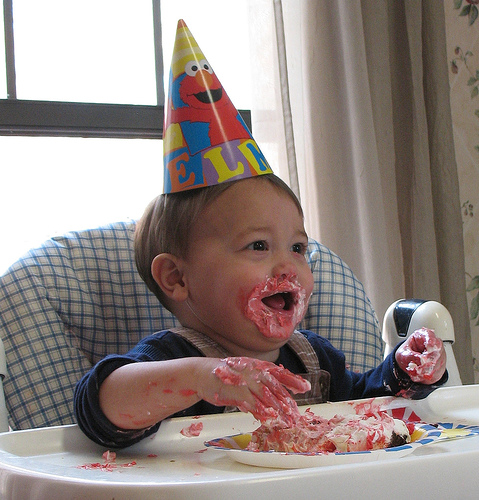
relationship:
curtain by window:
[305, 4, 479, 387] [1, 2, 321, 267]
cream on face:
[237, 279, 305, 335] [195, 183, 316, 345]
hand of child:
[205, 347, 300, 423] [74, 172, 447, 448]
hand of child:
[399, 325, 446, 385] [74, 172, 447, 448]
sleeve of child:
[71, 333, 208, 439] [74, 172, 447, 448]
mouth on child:
[259, 286, 299, 318] [74, 172, 447, 448]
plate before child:
[195, 403, 439, 480] [74, 172, 447, 448]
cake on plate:
[257, 403, 411, 454] [195, 403, 439, 480]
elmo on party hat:
[174, 62, 256, 152] [154, 16, 277, 197]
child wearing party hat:
[74, 172, 447, 448] [154, 16, 277, 197]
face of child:
[195, 183, 316, 345] [74, 172, 447, 448]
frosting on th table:
[85, 399, 234, 479] [0, 377, 477, 499]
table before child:
[0, 377, 477, 499] [74, 172, 447, 448]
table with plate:
[0, 377, 477, 499] [195, 403, 439, 480]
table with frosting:
[0, 377, 477, 499] [85, 399, 234, 479]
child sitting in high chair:
[74, 172, 447, 448] [3, 211, 475, 499]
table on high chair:
[0, 377, 477, 499] [3, 211, 475, 499]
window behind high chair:
[1, 2, 321, 267] [3, 211, 475, 499]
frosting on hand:
[167, 351, 319, 425] [205, 347, 300, 423]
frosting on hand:
[409, 332, 437, 383] [399, 325, 446, 385]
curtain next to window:
[305, 4, 479, 387] [1, 2, 321, 267]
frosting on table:
[85, 399, 234, 479] [0, 377, 477, 499]